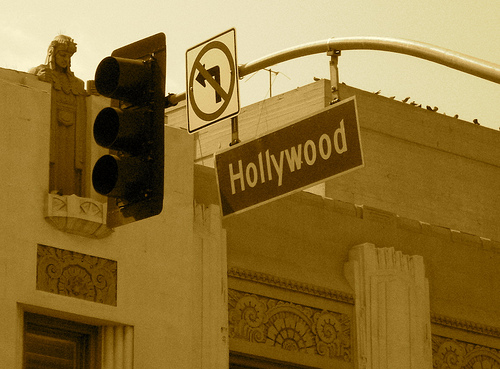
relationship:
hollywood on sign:
[226, 118, 348, 194] [213, 95, 365, 220]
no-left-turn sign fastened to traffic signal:
[184, 27, 240, 134] [93, 33, 166, 230]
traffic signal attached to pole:
[93, 33, 166, 230] [169, 37, 499, 104]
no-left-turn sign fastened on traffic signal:
[184, 27, 240, 134] [93, 33, 166, 230]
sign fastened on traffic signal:
[213, 95, 365, 220] [93, 33, 166, 230]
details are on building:
[35, 242, 118, 308] [2, 69, 500, 368]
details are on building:
[226, 287, 358, 368] [2, 69, 500, 368]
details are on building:
[431, 332, 499, 369] [2, 69, 500, 368]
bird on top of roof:
[472, 118, 480, 127] [240, 74, 498, 136]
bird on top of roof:
[426, 105, 440, 114] [240, 74, 498, 136]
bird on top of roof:
[402, 95, 411, 105] [240, 74, 498, 136]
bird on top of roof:
[372, 89, 382, 95] [240, 74, 498, 136]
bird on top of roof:
[311, 75, 322, 82] [240, 74, 498, 136]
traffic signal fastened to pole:
[93, 33, 166, 230] [169, 37, 499, 104]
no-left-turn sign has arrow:
[184, 27, 240, 134] [195, 65, 222, 104]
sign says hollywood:
[213, 95, 365, 220] [226, 118, 348, 194]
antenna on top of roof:
[256, 65, 288, 97] [240, 74, 498, 136]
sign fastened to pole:
[213, 95, 365, 220] [169, 37, 499, 104]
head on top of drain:
[47, 35, 77, 72] [45, 34, 119, 238]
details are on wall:
[35, 242, 118, 308] [1, 69, 194, 303]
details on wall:
[226, 287, 358, 368] [222, 232, 498, 369]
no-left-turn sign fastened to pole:
[184, 27, 240, 134] [169, 37, 499, 104]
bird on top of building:
[472, 118, 480, 127] [2, 69, 500, 368]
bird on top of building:
[426, 105, 440, 114] [2, 69, 500, 368]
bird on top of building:
[402, 95, 411, 105] [2, 69, 500, 368]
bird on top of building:
[372, 89, 382, 95] [2, 69, 500, 368]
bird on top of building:
[311, 75, 322, 82] [2, 69, 500, 368]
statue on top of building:
[32, 34, 98, 196] [2, 69, 500, 368]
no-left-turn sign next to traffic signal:
[184, 27, 240, 134] [93, 33, 166, 230]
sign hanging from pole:
[213, 95, 365, 220] [169, 37, 499, 104]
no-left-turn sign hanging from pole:
[184, 27, 240, 134] [169, 37, 499, 104]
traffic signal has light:
[93, 33, 166, 230] [94, 56, 153, 101]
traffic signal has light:
[93, 33, 166, 230] [92, 105, 146, 153]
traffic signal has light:
[93, 33, 166, 230] [90, 155, 146, 196]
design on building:
[226, 262, 359, 308] [2, 69, 500, 368]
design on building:
[303, 192, 499, 259] [2, 69, 500, 368]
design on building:
[43, 194, 115, 240] [2, 69, 500, 368]